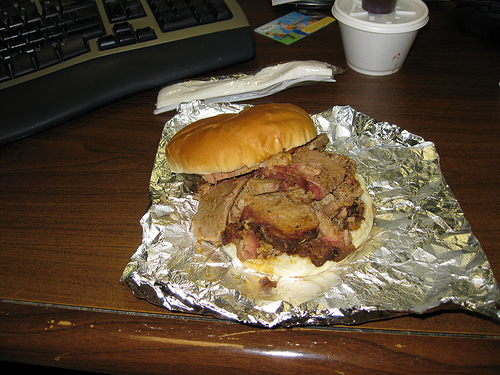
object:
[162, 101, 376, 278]
sandwhich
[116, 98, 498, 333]
foil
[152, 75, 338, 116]
fork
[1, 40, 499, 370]
table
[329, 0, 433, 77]
container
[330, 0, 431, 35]
lid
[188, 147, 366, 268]
beef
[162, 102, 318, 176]
bun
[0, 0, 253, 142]
keyboard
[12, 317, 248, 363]
scratches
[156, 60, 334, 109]
napkin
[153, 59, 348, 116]
plasticware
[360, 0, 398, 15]
sauce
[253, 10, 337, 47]
card